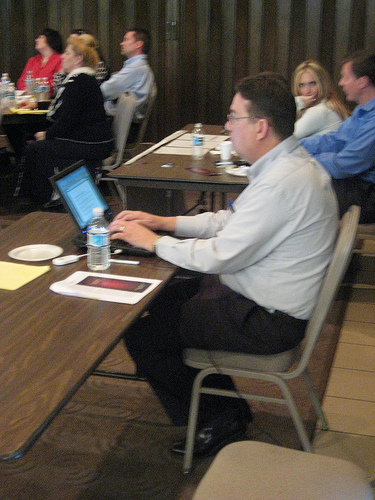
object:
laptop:
[48, 156, 155, 257]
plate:
[9, 243, 62, 264]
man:
[107, 71, 340, 459]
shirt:
[156, 135, 341, 317]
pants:
[123, 283, 310, 428]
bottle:
[86, 206, 112, 270]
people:
[285, 51, 375, 226]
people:
[28, 40, 114, 161]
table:
[0, 71, 53, 123]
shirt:
[300, 98, 375, 183]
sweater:
[45, 66, 115, 148]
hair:
[291, 61, 353, 123]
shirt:
[15, 51, 62, 95]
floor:
[0, 311, 313, 499]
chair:
[183, 205, 361, 473]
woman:
[292, 58, 354, 142]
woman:
[22, 33, 111, 201]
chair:
[77, 89, 138, 183]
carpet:
[77, 405, 186, 495]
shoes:
[169, 404, 254, 457]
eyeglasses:
[223, 110, 272, 125]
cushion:
[186, 342, 288, 372]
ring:
[119, 223, 127, 233]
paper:
[49, 270, 161, 304]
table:
[0, 211, 180, 464]